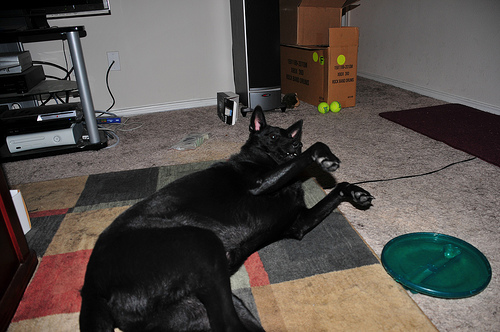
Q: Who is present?
A: No one.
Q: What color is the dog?
A: Black.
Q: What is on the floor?
A: Rug.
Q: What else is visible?
A: Frisbee.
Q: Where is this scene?
A: The living room.